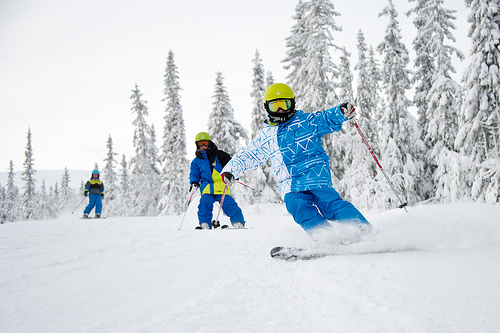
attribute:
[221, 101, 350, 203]
coat — white, blue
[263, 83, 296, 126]
helmet — yellow, yellow green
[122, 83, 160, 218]
tree — snow covered, snow coveed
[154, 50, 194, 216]
tree — snow covered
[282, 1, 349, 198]
tree — snow covered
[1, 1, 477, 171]
sky — white, grayish white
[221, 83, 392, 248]
kid — skiing, boy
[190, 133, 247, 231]
child — skiing, boy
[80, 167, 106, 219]
boy — skiing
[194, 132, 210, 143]
helmet — yellow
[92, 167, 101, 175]
helmet — blue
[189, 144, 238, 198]
jacket — blue, yellow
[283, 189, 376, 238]
pants — blue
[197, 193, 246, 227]
pants — blue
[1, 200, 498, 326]
snow — white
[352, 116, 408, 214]
ski pole — red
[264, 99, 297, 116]
goggles — yellow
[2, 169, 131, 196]
hill — snow covered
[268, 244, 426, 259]
ski — black